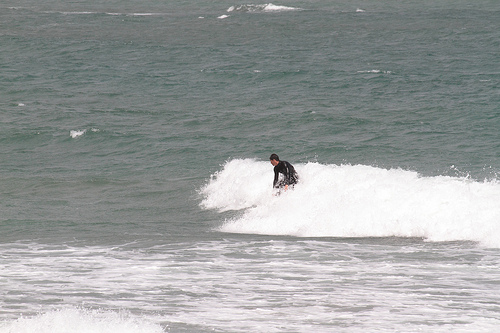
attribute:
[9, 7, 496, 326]
ocean view — large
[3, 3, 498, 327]
water — blue, green, white, alot, clear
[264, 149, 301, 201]
man — bent, young, surfing, facing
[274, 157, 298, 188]
wetsuit — black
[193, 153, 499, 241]
water wave — medium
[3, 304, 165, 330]
water wave — small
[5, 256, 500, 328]
splash — good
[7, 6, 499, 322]
ocean — here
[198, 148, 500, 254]
wave — crashing, cresting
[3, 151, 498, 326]
sea foam — here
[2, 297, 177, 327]
water — splashing up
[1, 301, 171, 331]
wave — very small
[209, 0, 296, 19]
wave — white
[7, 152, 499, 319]
suds — white